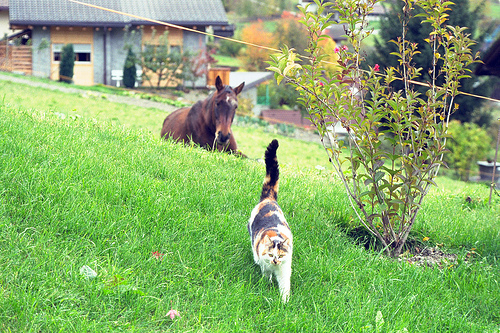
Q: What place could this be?
A: It is a lawn.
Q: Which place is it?
A: It is a lawn.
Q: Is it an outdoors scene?
A: Yes, it is outdoors.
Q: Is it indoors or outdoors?
A: It is outdoors.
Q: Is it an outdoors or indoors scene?
A: It is outdoors.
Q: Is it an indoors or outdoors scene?
A: It is outdoors.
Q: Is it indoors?
A: No, it is outdoors.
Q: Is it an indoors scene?
A: No, it is outdoors.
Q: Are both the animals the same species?
A: No, they are horses and cats.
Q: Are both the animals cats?
A: No, they are horses and cats.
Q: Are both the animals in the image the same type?
A: No, they are horses and cats.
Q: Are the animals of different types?
A: Yes, they are horses and cats.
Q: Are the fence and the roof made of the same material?
A: No, the fence is made of wood and the roof is made of metal.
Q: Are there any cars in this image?
A: No, there are no cars.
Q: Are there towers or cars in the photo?
A: No, there are no cars or towers.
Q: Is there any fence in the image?
A: Yes, there is a fence.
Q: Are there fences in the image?
A: Yes, there is a fence.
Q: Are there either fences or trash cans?
A: Yes, there is a fence.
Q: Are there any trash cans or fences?
A: Yes, there is a fence.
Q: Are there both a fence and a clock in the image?
A: No, there is a fence but no clocks.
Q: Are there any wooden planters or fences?
A: Yes, there is a wood fence.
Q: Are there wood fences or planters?
A: Yes, there is a wood fence.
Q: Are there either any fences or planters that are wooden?
A: Yes, the fence is wooden.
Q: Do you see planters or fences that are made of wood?
A: Yes, the fence is made of wood.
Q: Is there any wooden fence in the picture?
A: Yes, there is a wood fence.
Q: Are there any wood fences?
A: Yes, there is a wood fence.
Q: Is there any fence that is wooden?
A: Yes, there is a fence that is wooden.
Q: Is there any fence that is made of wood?
A: Yes, there is a fence that is made of wood.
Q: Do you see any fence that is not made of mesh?
A: Yes, there is a fence that is made of wood.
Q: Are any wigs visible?
A: No, there are no wigs.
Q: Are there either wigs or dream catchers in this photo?
A: No, there are no wigs or dream catchers.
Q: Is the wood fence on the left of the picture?
A: Yes, the fence is on the left of the image.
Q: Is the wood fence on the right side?
A: No, the fence is on the left of the image.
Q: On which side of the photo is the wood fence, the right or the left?
A: The fence is on the left of the image.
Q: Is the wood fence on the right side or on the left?
A: The fence is on the left of the image.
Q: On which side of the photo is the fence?
A: The fence is on the left of the image.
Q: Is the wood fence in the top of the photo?
A: Yes, the fence is in the top of the image.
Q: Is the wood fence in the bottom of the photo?
A: No, the fence is in the top of the image.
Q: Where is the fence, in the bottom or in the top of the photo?
A: The fence is in the top of the image.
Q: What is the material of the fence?
A: The fence is made of wood.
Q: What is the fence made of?
A: The fence is made of wood.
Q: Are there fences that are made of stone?
A: No, there is a fence but it is made of wood.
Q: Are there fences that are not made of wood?
A: No, there is a fence but it is made of wood.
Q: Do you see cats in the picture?
A: Yes, there is a cat.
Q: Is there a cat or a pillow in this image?
A: Yes, there is a cat.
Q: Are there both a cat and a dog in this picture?
A: No, there is a cat but no dogs.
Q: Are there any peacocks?
A: No, there are no peacocks.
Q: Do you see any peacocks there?
A: No, there are no peacocks.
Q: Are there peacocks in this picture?
A: No, there are no peacocks.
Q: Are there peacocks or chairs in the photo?
A: No, there are no peacocks or chairs.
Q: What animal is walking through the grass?
A: The cat is walking through the grass.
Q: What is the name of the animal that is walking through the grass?
A: The animal is a cat.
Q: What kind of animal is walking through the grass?
A: The animal is a cat.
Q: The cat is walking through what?
A: The cat is walking through the grass.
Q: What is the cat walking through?
A: The cat is walking through the grass.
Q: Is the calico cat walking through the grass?
A: Yes, the cat is walking through the grass.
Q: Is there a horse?
A: Yes, there is a horse.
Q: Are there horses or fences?
A: Yes, there is a horse.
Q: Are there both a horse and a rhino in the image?
A: No, there is a horse but no rhinos.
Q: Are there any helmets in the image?
A: No, there are no helmets.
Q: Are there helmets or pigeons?
A: No, there are no helmets or pigeons.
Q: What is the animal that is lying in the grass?
A: The animal is a horse.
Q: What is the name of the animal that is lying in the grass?
A: The animal is a horse.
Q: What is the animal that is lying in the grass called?
A: The animal is a horse.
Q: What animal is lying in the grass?
A: The animal is a horse.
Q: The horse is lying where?
A: The horse is lying in the grass.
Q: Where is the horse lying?
A: The horse is lying in the grass.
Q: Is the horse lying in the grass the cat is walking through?
A: Yes, the horse is lying in the grass.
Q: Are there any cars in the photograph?
A: No, there are no cars.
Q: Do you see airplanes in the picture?
A: No, there are no airplanes.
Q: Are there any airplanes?
A: No, there are no airplanes.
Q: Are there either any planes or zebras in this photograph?
A: No, there are no planes or zebras.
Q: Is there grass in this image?
A: Yes, there is grass.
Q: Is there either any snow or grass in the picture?
A: Yes, there is grass.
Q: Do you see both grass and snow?
A: No, there is grass but no snow.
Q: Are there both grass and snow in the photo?
A: No, there is grass but no snow.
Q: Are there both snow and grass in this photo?
A: No, there is grass but no snow.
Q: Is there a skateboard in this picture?
A: No, there are no skateboards.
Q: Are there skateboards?
A: No, there are no skateboards.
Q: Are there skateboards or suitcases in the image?
A: No, there are no skateboards or suitcases.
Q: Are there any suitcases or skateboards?
A: No, there are no skateboards or suitcases.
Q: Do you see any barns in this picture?
A: No, there are no barns.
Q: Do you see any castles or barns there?
A: No, there are no barns or castles.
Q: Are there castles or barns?
A: No, there are no barns or castles.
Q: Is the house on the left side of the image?
A: Yes, the house is on the left of the image.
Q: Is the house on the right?
A: No, the house is on the left of the image.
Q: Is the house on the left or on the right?
A: The house is on the left of the image.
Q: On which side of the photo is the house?
A: The house is on the left of the image.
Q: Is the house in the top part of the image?
A: Yes, the house is in the top of the image.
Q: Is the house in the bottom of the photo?
A: No, the house is in the top of the image.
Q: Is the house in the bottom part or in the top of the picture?
A: The house is in the top of the image.